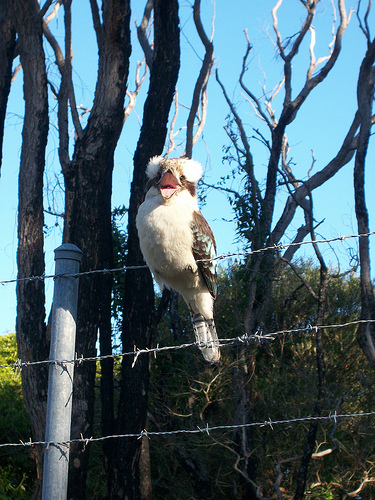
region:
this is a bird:
[137, 150, 205, 276]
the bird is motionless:
[135, 148, 214, 283]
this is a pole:
[27, 238, 88, 472]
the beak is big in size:
[156, 177, 176, 196]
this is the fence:
[83, 341, 155, 455]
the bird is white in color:
[142, 209, 185, 266]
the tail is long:
[189, 311, 219, 366]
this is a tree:
[65, 108, 114, 184]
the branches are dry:
[263, 26, 331, 97]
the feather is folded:
[192, 225, 211, 258]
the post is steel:
[48, 459, 86, 490]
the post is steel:
[37, 441, 88, 487]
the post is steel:
[49, 450, 71, 472]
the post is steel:
[57, 448, 95, 474]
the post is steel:
[24, 431, 81, 473]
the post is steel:
[41, 420, 110, 477]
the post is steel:
[24, 402, 70, 442]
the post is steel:
[48, 404, 100, 462]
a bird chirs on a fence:
[131, 150, 238, 358]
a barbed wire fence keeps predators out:
[3, 241, 372, 455]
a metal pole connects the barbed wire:
[43, 240, 104, 492]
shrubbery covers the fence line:
[130, 274, 372, 497]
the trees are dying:
[1, 2, 374, 342]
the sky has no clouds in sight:
[5, 26, 373, 256]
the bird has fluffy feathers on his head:
[141, 149, 222, 362]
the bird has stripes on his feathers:
[134, 139, 225, 369]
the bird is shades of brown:
[123, 153, 229, 363]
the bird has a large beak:
[129, 149, 227, 369]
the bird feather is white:
[130, 225, 209, 260]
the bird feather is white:
[125, 182, 215, 274]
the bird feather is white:
[136, 156, 279, 394]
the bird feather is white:
[144, 155, 189, 255]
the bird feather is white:
[141, 121, 232, 254]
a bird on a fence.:
[127, 153, 228, 365]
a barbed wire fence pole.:
[35, 232, 89, 498]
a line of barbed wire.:
[72, 396, 374, 465]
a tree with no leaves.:
[225, 3, 353, 271]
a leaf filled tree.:
[208, 54, 287, 270]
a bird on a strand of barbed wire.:
[86, 212, 373, 297]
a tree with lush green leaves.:
[0, 325, 31, 408]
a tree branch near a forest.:
[345, 1, 373, 286]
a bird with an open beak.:
[150, 160, 195, 209]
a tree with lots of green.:
[147, 252, 371, 492]